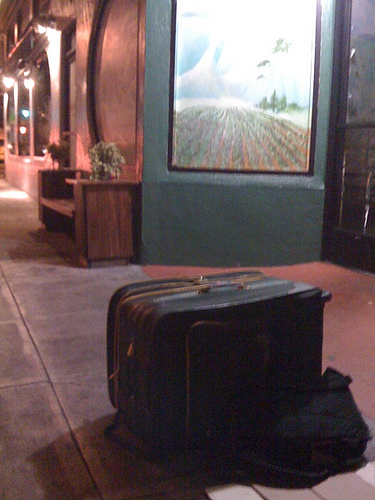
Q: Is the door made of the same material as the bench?
A: Yes, both the door and the bench are made of wood.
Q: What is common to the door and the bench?
A: The material, both the door and the bench are wooden.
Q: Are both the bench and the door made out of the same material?
A: Yes, both the bench and the door are made of wood.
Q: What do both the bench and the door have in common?
A: The material, both the bench and the door are wooden.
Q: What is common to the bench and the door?
A: The material, both the bench and the door are wooden.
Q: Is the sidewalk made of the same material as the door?
A: No, the sidewalk is made of cement and the door is made of wood.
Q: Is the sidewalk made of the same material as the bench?
A: No, the sidewalk is made of concrete and the bench is made of wood.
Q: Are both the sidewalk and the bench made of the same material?
A: No, the sidewalk is made of concrete and the bench is made of wood.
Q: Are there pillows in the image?
A: No, there are no pillows.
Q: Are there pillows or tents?
A: No, there are no pillows or tents.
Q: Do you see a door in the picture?
A: Yes, there is a door.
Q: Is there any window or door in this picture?
A: Yes, there is a door.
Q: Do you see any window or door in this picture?
A: Yes, there is a door.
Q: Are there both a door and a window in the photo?
A: Yes, there are both a door and a window.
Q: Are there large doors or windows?
A: Yes, there is a large door.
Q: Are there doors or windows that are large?
A: Yes, the door is large.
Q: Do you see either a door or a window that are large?
A: Yes, the door is large.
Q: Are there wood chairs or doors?
A: Yes, there is a wood door.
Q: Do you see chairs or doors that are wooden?
A: Yes, the door is wooden.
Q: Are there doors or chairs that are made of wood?
A: Yes, the door is made of wood.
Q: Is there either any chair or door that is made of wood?
A: Yes, the door is made of wood.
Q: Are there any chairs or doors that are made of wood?
A: Yes, the door is made of wood.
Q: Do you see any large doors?
A: Yes, there is a large door.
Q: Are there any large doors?
A: Yes, there is a large door.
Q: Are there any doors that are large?
A: Yes, there is a door that is large.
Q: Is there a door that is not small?
A: Yes, there is a large door.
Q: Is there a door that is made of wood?
A: Yes, there is a door that is made of wood.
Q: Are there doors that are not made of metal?
A: Yes, there is a door that is made of wood.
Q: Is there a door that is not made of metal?
A: Yes, there is a door that is made of wood.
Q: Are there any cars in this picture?
A: No, there are no cars.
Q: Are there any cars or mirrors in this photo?
A: No, there are no cars or mirrors.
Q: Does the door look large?
A: Yes, the door is large.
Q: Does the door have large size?
A: Yes, the door is large.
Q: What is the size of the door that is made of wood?
A: The door is large.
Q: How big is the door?
A: The door is large.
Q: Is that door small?
A: No, the door is large.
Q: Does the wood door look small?
A: No, the door is large.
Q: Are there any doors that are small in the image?
A: No, there is a door but it is large.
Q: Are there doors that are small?
A: No, there is a door but it is large.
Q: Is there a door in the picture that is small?
A: No, there is a door but it is large.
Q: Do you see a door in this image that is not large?
A: No, there is a door but it is large.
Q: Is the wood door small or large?
A: The door is large.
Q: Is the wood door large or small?
A: The door is large.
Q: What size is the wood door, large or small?
A: The door is large.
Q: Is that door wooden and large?
A: Yes, the door is wooden and large.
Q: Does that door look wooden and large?
A: Yes, the door is wooden and large.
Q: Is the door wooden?
A: Yes, the door is wooden.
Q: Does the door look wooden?
A: Yes, the door is wooden.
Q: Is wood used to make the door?
A: Yes, the door is made of wood.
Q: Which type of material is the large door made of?
A: The door is made of wood.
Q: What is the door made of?
A: The door is made of wood.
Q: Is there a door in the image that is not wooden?
A: No, there is a door but it is wooden.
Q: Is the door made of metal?
A: No, the door is made of wood.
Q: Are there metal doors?
A: No, there is a door but it is made of wood.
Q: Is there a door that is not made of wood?
A: No, there is a door but it is made of wood.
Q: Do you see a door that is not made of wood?
A: No, there is a door but it is made of wood.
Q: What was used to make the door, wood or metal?
A: The door is made of wood.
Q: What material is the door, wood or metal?
A: The door is made of wood.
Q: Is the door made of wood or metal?
A: The door is made of wood.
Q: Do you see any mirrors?
A: No, there are no mirrors.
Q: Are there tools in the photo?
A: No, there are no tools.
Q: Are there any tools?
A: No, there are no tools.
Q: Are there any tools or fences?
A: No, there are no tools or fences.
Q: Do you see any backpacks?
A: Yes, there is a backpack.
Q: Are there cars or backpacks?
A: Yes, there is a backpack.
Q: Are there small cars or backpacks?
A: Yes, there is a small backpack.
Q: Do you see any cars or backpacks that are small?
A: Yes, the backpack is small.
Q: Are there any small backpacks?
A: Yes, there is a small backpack.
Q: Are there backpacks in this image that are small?
A: Yes, there is a backpack that is small.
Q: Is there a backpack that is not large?
A: Yes, there is a small backpack.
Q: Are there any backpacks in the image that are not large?
A: Yes, there is a small backpack.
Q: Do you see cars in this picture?
A: No, there are no cars.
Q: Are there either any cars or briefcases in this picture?
A: No, there are no cars or briefcases.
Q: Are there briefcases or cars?
A: No, there are no cars or briefcases.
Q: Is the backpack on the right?
A: Yes, the backpack is on the right of the image.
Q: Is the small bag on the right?
A: Yes, the backpack is on the right of the image.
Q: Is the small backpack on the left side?
A: No, the backpack is on the right of the image.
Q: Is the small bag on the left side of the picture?
A: No, the backpack is on the right of the image.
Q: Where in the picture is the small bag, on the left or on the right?
A: The backpack is on the right of the image.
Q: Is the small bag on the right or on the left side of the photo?
A: The backpack is on the right of the image.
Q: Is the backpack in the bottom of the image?
A: Yes, the backpack is in the bottom of the image.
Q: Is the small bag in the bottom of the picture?
A: Yes, the backpack is in the bottom of the image.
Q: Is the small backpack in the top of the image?
A: No, the backpack is in the bottom of the image.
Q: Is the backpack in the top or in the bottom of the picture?
A: The backpack is in the bottom of the image.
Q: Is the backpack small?
A: Yes, the backpack is small.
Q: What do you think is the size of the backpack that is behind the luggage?
A: The backpack is small.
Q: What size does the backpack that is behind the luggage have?
A: The backpack has small size.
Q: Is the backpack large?
A: No, the backpack is small.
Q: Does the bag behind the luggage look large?
A: No, the backpack is small.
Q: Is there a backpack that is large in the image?
A: No, there is a backpack but it is small.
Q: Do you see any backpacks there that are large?
A: No, there is a backpack but it is small.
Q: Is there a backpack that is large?
A: No, there is a backpack but it is small.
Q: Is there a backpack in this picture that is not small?
A: No, there is a backpack but it is small.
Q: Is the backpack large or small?
A: The backpack is small.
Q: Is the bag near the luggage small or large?
A: The backpack is small.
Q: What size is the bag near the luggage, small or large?
A: The backpack is small.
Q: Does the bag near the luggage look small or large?
A: The backpack is small.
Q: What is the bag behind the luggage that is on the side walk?
A: The bag is a backpack.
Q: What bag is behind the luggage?
A: The bag is a backpack.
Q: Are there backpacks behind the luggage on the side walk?
A: Yes, there is a backpack behind the luggage.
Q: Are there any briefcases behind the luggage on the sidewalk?
A: No, there is a backpack behind the luggage.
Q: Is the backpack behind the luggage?
A: Yes, the backpack is behind the luggage.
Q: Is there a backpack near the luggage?
A: Yes, there is a backpack near the luggage.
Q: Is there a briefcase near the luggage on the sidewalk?
A: No, there is a backpack near the luggage.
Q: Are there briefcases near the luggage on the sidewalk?
A: No, there is a backpack near the luggage.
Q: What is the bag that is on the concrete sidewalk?
A: The bag is a backpack.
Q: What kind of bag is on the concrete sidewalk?
A: The bag is a backpack.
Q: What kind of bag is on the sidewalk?
A: The bag is a backpack.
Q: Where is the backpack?
A: The backpack is on the sidewalk.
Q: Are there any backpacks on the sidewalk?
A: Yes, there is a backpack on the sidewalk.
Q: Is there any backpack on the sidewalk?
A: Yes, there is a backpack on the sidewalk.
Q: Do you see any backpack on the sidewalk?
A: Yes, there is a backpack on the sidewalk.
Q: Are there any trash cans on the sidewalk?
A: No, there is a backpack on the sidewalk.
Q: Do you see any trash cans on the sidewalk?
A: No, there is a backpack on the sidewalk.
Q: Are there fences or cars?
A: No, there are no cars or fences.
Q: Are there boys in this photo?
A: No, there are no boys.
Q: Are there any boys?
A: No, there are no boys.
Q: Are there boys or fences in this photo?
A: No, there are no boys or fences.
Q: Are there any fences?
A: No, there are no fences.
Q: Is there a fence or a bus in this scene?
A: No, there are no fences or buses.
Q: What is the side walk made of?
A: The side walk is made of concrete.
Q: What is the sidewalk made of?
A: The side walk is made of concrete.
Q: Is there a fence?
A: No, there are no fences.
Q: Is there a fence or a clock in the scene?
A: No, there are no fences or clocks.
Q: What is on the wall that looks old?
A: The poster is on the wall.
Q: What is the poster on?
A: The poster is on the wall.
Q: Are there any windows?
A: Yes, there is a window.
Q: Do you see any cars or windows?
A: Yes, there is a window.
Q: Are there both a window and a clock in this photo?
A: No, there is a window but no clocks.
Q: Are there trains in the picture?
A: No, there are no trains.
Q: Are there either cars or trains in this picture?
A: No, there are no trains or cars.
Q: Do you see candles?
A: No, there are no candles.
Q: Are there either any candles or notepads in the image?
A: No, there are no candles or notepads.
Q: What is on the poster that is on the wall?
A: The plants are on the poster.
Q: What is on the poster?
A: The plants are on the poster.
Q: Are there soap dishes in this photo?
A: No, there are no soap dishes.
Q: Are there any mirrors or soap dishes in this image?
A: No, there are no soap dishes or mirrors.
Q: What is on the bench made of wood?
A: The seat is on the bench.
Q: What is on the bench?
A: The seat is on the bench.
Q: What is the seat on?
A: The seat is on the bench.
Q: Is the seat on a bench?
A: Yes, the seat is on a bench.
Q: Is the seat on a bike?
A: No, the seat is on a bench.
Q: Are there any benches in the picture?
A: Yes, there is a bench.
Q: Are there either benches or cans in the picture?
A: Yes, there is a bench.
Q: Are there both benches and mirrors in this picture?
A: No, there is a bench but no mirrors.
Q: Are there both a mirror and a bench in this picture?
A: No, there is a bench but no mirrors.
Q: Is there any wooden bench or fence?
A: Yes, there is a wood bench.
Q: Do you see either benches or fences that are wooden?
A: Yes, the bench is wooden.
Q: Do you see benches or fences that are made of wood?
A: Yes, the bench is made of wood.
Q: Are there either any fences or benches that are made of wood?
A: Yes, the bench is made of wood.